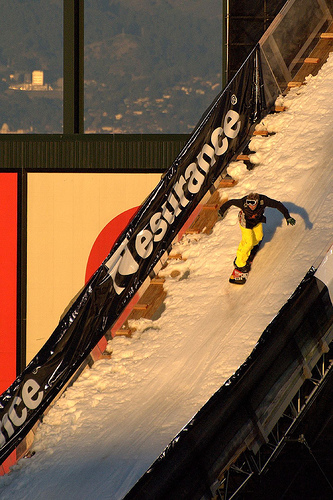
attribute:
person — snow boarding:
[215, 181, 302, 286]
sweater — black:
[240, 198, 266, 225]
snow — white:
[166, 326, 200, 355]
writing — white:
[150, 217, 173, 244]